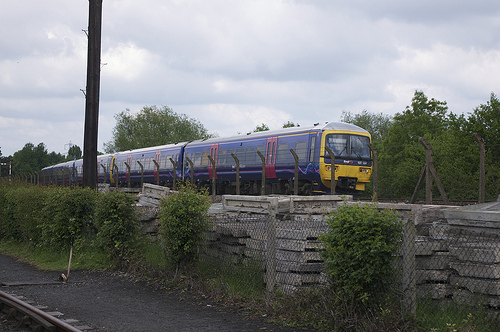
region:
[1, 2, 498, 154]
gray clouds in sky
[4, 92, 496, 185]
green leaves on trees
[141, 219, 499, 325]
metal chain link fence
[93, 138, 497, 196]
fence with bent posts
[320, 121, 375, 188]
yellow front of train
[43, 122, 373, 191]
red doors on blue train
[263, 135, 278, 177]
red doors with windows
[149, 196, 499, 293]
rows of stacked squares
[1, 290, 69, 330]
metal rail of train track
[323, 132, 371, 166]
windows on front of train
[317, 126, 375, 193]
the yellow front of a train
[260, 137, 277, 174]
the doors on a train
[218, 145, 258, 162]
windows on a train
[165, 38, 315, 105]
clouds in the sky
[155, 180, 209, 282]
a bush with green leaves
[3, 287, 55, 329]
railroad rail with ties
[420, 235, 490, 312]
metal chain link fence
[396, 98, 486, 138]
green leaves on trees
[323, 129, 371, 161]
the windshield on a train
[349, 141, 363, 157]
a windshield wiper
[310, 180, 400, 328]
Green bush by a wall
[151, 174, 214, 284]
Green bush by a wall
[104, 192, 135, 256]
Green bush by a wall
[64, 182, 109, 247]
Green bush by a wall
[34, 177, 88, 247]
Green bush by a wall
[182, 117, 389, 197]
Blue and red train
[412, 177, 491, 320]
Part of concrete wall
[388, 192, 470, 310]
Part of concrete wall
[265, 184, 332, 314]
Part of concrete wall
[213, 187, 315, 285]
Part of concrete wall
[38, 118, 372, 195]
blue yellow and red train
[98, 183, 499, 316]
wooden pallets on side of train tracks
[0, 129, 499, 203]
metal and wood fence along train tracks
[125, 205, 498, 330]
black chain fence in front of pallets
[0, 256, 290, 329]
dirt next to train tracks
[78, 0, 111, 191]
tall black pole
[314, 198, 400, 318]
one small bush in front of fence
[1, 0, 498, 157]
big fluffy clouds in sky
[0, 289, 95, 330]
edge of the train track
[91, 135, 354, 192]
The train is on the tracks.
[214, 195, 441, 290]
Concrete blocks on side of fence.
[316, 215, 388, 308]
Bushes growing on the fence.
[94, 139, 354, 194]
A fence along side the train.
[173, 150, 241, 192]
Wooden posts to hold fence up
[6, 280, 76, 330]
Part of tracks on the ground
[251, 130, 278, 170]
Red door on the train.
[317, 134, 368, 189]
Front of the train is yellow.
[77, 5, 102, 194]
A tall wooden pole on side of tracks.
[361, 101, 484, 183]
Green trees behind the fence.